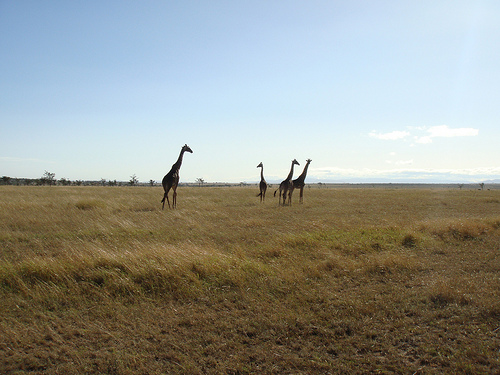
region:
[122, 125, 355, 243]
four giraffes on a field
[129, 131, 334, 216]
giraffes are in an open field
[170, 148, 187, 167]
long neck of giraffe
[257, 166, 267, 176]
long neck of giraffe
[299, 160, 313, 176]
long neck of giraffe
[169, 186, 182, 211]
front feet of giraffe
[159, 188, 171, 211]
back feet of giraffe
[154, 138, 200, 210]
giraffe face to the right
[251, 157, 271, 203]
giraffe face to the left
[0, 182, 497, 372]
field is covered with dry grass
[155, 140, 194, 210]
tall giraffe standing alone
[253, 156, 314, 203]
a group of three giraffes .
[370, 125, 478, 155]
white clouds in the background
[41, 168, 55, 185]
tree in the background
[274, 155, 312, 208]
two giraffes that are close to eachother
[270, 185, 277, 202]
tail of a giraffe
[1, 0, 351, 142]
blue and clear skies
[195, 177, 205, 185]
tree in the background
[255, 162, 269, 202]
a giraffe looking away from the other giraffes.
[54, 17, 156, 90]
blue sky in the photo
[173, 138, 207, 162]
head of the giraffe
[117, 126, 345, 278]
many different giraffes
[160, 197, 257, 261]
grass under the giraffes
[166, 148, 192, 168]
neck of the giraffe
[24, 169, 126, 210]
trees in the distance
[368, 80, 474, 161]
clouds in the sky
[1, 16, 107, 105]
sky with no clouds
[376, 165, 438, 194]
hills in the distance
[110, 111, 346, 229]
The giraffes are in the wild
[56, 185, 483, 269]
The giraffes are on grass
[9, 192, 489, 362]
Most of the grass is brown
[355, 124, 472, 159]
Just a few clouds in the sky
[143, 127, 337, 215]
There are four giraffes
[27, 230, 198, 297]
The grass is blowing to the left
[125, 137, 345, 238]
Giraffe in grassy plain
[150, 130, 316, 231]
Giraffe in grassy plain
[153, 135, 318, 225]
Giraffe in grassy plain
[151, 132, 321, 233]
Giraffe in grassy plain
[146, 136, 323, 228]
Giraffe in grassy plain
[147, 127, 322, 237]
Giraffe in grassy plain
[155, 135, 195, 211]
giraffe standing in field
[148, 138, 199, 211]
giraffe on left is tall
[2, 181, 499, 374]
field is slightly brown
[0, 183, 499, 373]
grass in field is dry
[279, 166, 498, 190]
mountains in distance behind field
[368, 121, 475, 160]
small clouds in sky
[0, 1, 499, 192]
sky is mostly clear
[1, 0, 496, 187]
sky is lighter blue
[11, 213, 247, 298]
stalks of grass billowing